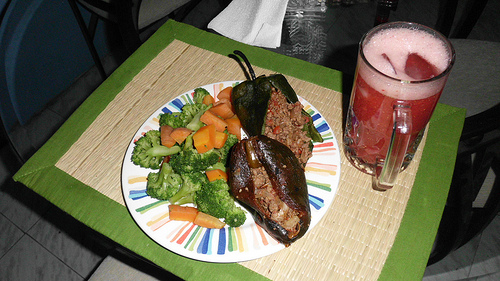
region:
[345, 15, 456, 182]
clear glass mug with pink drink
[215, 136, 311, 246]
roasted pepper stuffed with rice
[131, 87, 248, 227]
steamed broccoli and carrots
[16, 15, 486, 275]
wicker placemat bounded by green cotton border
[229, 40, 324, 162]
roasted green pepper stuffed with brown rice and flecks of tomato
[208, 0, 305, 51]
white napkin on table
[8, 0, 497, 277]
indoor kitchen scene with food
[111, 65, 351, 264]
round white plate with orange, blue and green stripes on edge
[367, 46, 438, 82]
ice floating in frothy drink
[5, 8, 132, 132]
back of blue chair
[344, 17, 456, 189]
a glass of red soda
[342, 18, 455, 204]
a glass of red pop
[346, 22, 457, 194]
a drink with ice cubes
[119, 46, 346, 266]
dinner on a plate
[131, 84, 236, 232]
brocolli and carrots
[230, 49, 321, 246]
stuffed green peppers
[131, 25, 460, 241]
a healthy supper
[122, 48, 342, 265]
cooked food on a plate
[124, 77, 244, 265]
vegetables on a plate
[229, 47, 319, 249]
green peppers filled with meat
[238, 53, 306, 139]
Stuffed green pepper on plate.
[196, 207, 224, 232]
Piece of carrot on plate.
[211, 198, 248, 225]
Green broccoli on plate.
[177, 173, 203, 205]
Green broccoli sitting plate.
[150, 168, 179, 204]
Green broccoli sitting on plate.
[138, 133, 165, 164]
Green broccoli sitting on plate.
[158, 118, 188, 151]
Piece of cut carrot on plate.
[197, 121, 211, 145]
Orange carrot sitting on plate.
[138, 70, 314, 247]
Food on top of multi colored plate.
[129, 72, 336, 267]
Plate on top of brown and green place mat.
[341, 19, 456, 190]
a glass mug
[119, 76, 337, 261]
a colorful plate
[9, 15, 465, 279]
a green and tan place mat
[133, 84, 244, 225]
broccoli and carrots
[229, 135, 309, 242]
meat on the plate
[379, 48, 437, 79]
ice cubes in the drink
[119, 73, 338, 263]
a plate of food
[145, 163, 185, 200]
a piece of broccoli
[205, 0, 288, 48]
a white towel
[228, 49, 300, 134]
the top of a pepper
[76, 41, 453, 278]
a plate of food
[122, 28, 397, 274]
a plate of cooked food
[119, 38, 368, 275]
a plate with brocolli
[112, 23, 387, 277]
a plate with green brocolli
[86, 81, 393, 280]
a plate with cooked brocolli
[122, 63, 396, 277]
a plate with carrots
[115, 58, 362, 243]
a plate with sliced carrots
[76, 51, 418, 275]
a plate with cooked carrots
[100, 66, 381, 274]
a plate with sliced cooked carrots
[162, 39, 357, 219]
cooked stuffed peppers